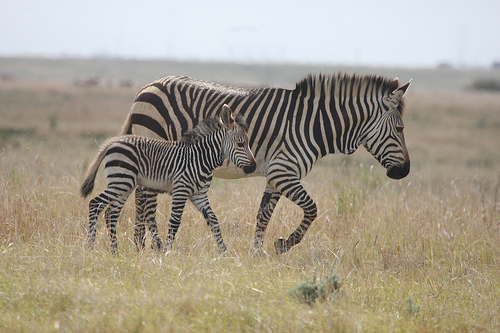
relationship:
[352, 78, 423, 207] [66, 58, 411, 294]
head of zebra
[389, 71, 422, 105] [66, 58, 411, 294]
ear of zebra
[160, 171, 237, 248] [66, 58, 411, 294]
leg of zebra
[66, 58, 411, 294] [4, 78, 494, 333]
zebra in grass